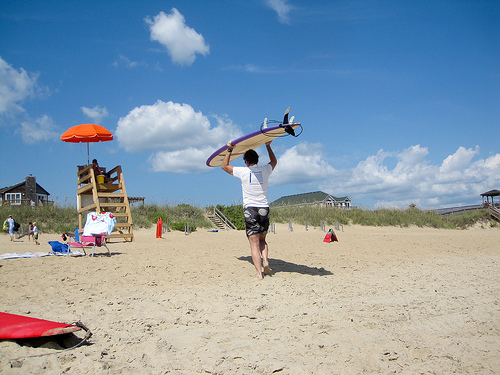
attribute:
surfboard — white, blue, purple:
[203, 104, 308, 178]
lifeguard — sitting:
[83, 157, 111, 191]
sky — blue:
[1, 2, 499, 205]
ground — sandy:
[1, 222, 496, 375]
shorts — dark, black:
[241, 204, 273, 243]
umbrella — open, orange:
[58, 119, 115, 167]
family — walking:
[3, 212, 42, 249]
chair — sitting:
[60, 211, 120, 261]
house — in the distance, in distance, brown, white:
[1, 172, 52, 212]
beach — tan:
[1, 200, 499, 374]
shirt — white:
[229, 159, 278, 215]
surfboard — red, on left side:
[0, 297, 92, 351]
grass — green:
[1, 194, 495, 237]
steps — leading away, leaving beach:
[199, 205, 240, 231]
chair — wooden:
[74, 157, 138, 243]